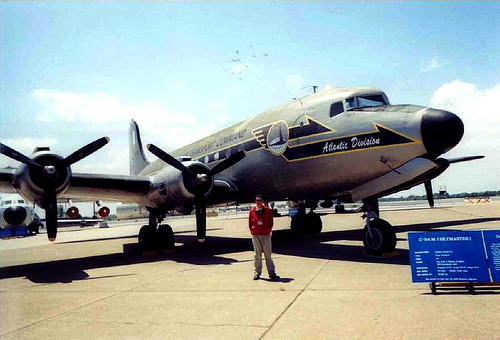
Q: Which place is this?
A: It is a runway.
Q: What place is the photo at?
A: It is at the runway.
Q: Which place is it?
A: It is a runway.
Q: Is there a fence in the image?
A: No, there are no fences.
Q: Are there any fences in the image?
A: No, there are no fences.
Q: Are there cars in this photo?
A: No, there are no cars.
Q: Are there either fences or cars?
A: No, there are no cars or fences.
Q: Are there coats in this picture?
A: Yes, there is a coat.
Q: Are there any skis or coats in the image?
A: Yes, there is a coat.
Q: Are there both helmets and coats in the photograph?
A: No, there is a coat but no helmets.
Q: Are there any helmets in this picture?
A: No, there are no helmets.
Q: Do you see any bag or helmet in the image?
A: No, there are no helmets or bags.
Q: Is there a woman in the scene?
A: No, there are no women.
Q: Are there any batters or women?
A: No, there are no women or batters.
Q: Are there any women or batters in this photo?
A: No, there are no women or batters.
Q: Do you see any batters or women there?
A: No, there are no women or batters.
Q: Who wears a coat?
A: The man wears a coat.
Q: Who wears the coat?
A: The man wears a coat.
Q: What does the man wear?
A: The man wears a coat.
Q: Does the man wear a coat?
A: Yes, the man wears a coat.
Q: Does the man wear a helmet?
A: No, the man wears a coat.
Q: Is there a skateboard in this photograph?
A: No, there are no skateboards.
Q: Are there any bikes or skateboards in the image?
A: No, there are no skateboards or bikes.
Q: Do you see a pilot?
A: No, there are no pilots.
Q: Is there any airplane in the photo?
A: Yes, there is an airplane.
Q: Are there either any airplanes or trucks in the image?
A: Yes, there is an airplane.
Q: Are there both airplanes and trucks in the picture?
A: No, there is an airplane but no trucks.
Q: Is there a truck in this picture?
A: No, there are no trucks.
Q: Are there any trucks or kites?
A: No, there are no trucks or kites.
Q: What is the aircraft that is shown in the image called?
A: The aircraft is an airplane.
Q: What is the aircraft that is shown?
A: The aircraft is an airplane.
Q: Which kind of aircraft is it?
A: The aircraft is an airplane.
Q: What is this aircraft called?
A: This is an airplane.